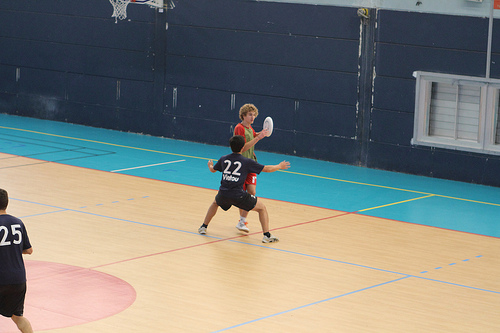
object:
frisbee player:
[197, 133, 290, 246]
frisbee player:
[227, 103, 271, 234]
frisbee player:
[0, 186, 37, 332]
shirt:
[1, 213, 31, 286]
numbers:
[1, 224, 23, 249]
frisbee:
[262, 116, 273, 137]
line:
[351, 193, 435, 212]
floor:
[0, 111, 498, 333]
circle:
[1, 258, 140, 333]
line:
[418, 254, 485, 275]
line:
[410, 275, 499, 295]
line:
[87, 238, 226, 269]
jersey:
[212, 152, 266, 198]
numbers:
[223, 160, 242, 176]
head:
[238, 103, 259, 125]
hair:
[238, 103, 259, 121]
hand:
[258, 130, 271, 139]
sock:
[263, 232, 271, 239]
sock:
[200, 223, 209, 228]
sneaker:
[261, 234, 280, 243]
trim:
[272, 238, 277, 241]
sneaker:
[198, 224, 208, 234]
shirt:
[233, 122, 259, 164]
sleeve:
[234, 127, 246, 138]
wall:
[0, 0, 500, 188]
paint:
[329, 185, 345, 192]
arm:
[249, 159, 291, 173]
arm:
[208, 157, 222, 174]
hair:
[228, 135, 245, 153]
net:
[109, 1, 130, 24]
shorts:
[214, 188, 258, 212]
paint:
[224, 42, 237, 53]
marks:
[356, 19, 361, 94]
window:
[411, 68, 500, 159]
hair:
[2, 191, 8, 209]